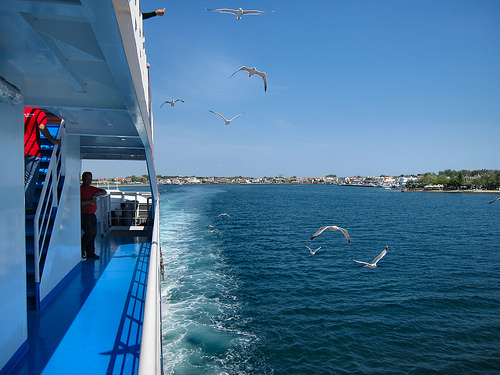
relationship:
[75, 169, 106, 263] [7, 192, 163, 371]
man standing on deck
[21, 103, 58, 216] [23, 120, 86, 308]
man walking up steps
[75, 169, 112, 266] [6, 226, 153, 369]
man standing on deck